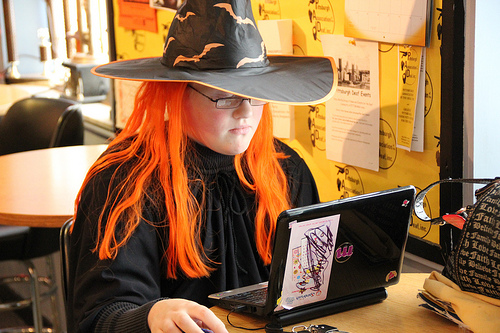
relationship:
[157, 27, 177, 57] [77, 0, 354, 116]
bat on hat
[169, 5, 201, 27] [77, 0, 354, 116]
bat on hat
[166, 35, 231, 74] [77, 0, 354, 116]
bat on hat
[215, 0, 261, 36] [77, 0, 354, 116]
bat on hat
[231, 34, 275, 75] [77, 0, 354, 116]
bat on hat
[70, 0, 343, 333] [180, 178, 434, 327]
kid using laptop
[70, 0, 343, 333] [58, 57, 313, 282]
kid has hair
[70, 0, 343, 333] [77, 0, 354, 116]
kid has hat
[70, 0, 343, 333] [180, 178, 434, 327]
kid working on laptop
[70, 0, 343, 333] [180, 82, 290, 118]
kid wearing eyeglasses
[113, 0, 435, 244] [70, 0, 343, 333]
bullentin board next to kid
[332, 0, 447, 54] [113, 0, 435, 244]
paper attached to bullentin board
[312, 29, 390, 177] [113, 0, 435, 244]
paper attached to bullentin board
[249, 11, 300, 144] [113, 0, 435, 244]
paper attached to bullentin board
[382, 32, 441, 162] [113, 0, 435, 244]
paper attached to bullentin board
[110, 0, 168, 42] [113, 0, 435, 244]
paper attached to bullentin board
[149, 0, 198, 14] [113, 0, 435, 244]
paper attached to bullentin board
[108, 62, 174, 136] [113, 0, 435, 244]
paper attached to bullentin board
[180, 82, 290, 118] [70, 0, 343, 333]
eyeglasses on kid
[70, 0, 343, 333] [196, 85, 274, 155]
kid has face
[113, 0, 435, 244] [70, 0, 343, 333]
bullentin board behind kid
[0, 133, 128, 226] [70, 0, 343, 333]
table behind kid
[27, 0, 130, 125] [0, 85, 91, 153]
window behind chair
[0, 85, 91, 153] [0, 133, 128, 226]
chair near table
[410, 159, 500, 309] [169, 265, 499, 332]
purse on table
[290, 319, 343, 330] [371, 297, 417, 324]
keys on table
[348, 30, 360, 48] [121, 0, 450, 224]
pin on bullentin board